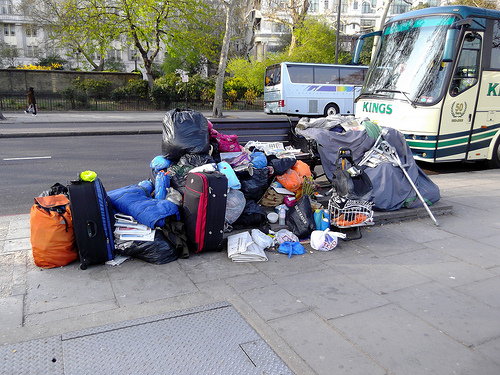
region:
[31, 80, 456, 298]
a pile of random stuff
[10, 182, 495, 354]
the sidewalk is gray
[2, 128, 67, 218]
the road has a white line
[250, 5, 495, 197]
buses are parked on the road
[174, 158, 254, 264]
a black and red siutcase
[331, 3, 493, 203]
the bus is green and white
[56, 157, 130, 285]
a black and blue suitcase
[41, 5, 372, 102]
the trees are green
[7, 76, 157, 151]
a person walking on the sidewalk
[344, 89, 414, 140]
the bus says kings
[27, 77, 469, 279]
The bags and papers on the side walk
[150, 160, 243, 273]
the suitcase is black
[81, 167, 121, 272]
the lining is blue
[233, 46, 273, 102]
the sky is green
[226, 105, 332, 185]
the bench is brown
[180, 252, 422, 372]
the street is gray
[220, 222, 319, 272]
the newspaper is on the ground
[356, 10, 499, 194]
the bus is blue and white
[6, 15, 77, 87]
the building is white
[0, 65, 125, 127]
a person is walking at the sidewalk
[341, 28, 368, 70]
a side view mirror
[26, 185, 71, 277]
an orange bag on the sidewalk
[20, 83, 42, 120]
a person on the sidewalk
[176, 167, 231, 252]
a black and red suitcase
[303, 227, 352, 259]
a white plastic bag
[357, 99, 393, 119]
green writing on the bus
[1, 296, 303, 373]
a metal grate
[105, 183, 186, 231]
a blue coat in a pile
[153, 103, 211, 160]
a large black trash bag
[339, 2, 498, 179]
bus on a street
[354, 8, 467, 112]
front windshield of a vehicle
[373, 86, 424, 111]
windshield wiper on a vehicle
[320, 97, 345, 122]
rear wheel on a vehicle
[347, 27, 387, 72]
side rear view mirror on a vehicle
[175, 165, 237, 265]
black and red suitcase on a sidewalk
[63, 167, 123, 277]
black and blue suitcase on a sidewalk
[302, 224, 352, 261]
white bag on a sidewalk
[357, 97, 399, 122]
name on the front of a bus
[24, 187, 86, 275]
orange bag on a sidewalk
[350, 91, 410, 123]
bus has green letters on it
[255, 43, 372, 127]
white bus parked on side of street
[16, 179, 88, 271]
orange bag on the ground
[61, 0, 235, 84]
green leaves on the tree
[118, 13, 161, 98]
branches are brown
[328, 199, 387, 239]
the basket is white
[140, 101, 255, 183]
a garbage bag is on top of the luggage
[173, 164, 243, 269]
bag is pink and black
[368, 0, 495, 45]
top of bus is blue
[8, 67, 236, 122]
metal fence is in front of building